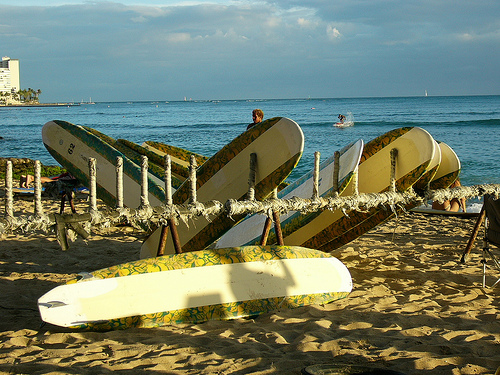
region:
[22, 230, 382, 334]
yellow green and beige surf board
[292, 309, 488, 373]
shadows on the sand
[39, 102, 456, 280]
lots of surf boards leaning up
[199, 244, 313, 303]
shadow of a person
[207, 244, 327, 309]
shadow on a surf board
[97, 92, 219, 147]
ocean water in the distance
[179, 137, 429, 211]
sticks holding up surf boards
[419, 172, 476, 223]
woman sitting on the sand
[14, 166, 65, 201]
person's two tanned feet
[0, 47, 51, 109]
tall building with palm trees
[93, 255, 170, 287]
floral design on side of surfboard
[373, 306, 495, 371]
track made on sandy beach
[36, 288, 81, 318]
tail on end of surfboard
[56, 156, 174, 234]
wooden surfboard holder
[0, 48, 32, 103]
tall building in the distance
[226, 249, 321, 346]
shadow of a man on the surfboard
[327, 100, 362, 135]
man standing on surfboard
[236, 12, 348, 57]
clouds in sky in photo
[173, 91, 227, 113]
sailboats in the distance of photo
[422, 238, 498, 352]
area of sand on right of photo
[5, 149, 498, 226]
rack to hold surfboards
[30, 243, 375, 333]
surfboard on ground near rack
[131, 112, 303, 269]
surfboard in storage rack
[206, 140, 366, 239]
surfboard in storage rack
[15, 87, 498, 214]
blue ocean in background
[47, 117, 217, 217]
surfboards in surfboard rack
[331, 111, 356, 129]
person on surfboard in ocean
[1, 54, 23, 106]
tall building in distance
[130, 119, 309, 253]
brown and white surfboard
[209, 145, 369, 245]
green and white surfboard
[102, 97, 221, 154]
the water is blue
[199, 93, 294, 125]
the water is blue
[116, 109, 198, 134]
the water is blue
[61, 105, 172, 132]
the water is blue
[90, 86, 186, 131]
the water is blue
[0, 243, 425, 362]
a surfboard on the ground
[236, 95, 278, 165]
a man at the beach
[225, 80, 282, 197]
a man at the beach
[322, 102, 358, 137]
a person is surfing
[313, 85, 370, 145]
a person is surfing